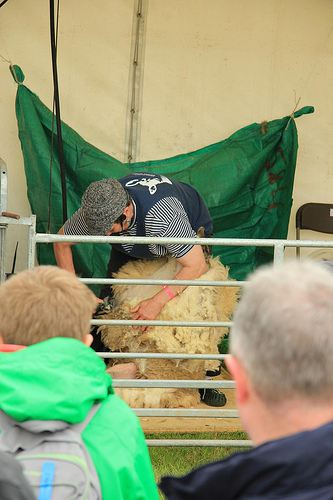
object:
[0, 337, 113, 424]
hood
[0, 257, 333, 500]
people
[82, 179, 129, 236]
hat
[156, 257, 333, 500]
man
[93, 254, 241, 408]
sheep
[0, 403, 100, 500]
backpack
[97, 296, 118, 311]
sheep shears